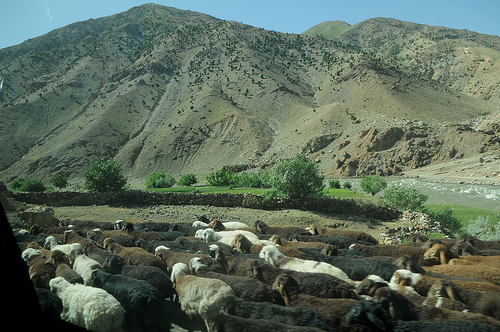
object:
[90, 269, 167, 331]
sheep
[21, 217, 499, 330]
herd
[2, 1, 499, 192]
mountain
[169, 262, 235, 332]
sheep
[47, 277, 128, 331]
sheep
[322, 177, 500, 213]
river